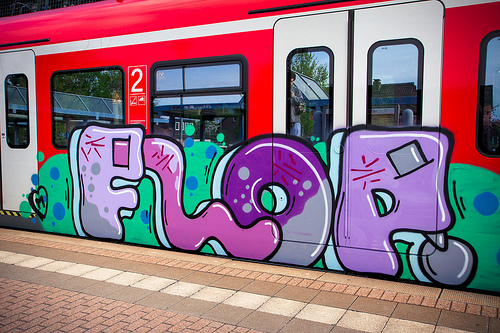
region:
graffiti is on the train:
[12, 76, 484, 291]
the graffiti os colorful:
[20, 74, 482, 317]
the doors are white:
[262, 8, 433, 257]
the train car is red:
[0, 1, 478, 171]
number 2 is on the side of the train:
[100, 54, 171, 123]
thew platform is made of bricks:
[57, 250, 329, 325]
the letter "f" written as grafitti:
[66, 124, 146, 242]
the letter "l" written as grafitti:
[140, 134, 282, 261]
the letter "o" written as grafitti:
[211, 135, 330, 269]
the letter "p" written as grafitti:
[323, 121, 454, 281]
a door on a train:
[270, 0, 440, 255]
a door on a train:
[0, 49, 42, 219]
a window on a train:
[48, 65, 124, 150]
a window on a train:
[150, 57, 248, 152]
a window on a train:
[372, 42, 419, 157]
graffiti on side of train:
[63, 118, 144, 241]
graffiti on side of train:
[136, 134, 283, 268]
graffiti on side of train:
[221, 133, 333, 262]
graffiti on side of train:
[340, 124, 450, 279]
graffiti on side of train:
[420, 223, 469, 287]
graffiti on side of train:
[21, 148, 78, 233]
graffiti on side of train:
[119, 170, 164, 246]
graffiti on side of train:
[386, 153, 493, 297]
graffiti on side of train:
[28, 119, 499, 303]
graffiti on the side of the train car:
[27, 110, 497, 277]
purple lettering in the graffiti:
[67, 128, 468, 280]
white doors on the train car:
[1, 18, 453, 285]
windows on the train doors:
[4, 43, 427, 183]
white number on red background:
[130, 68, 149, 96]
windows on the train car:
[51, 34, 499, 166]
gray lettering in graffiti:
[388, 139, 476, 284]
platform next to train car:
[2, 226, 489, 331]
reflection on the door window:
[291, 55, 324, 137]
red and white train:
[3, 5, 499, 280]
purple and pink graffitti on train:
[70, 126, 455, 246]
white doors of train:
[275, 1, 443, 258]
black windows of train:
[52, 30, 498, 168]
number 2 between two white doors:
[126, 64, 146, 94]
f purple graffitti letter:
[69, 125, 139, 236]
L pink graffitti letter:
[101, 137, 283, 260]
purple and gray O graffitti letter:
[211, 138, 333, 265]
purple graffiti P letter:
[328, 122, 450, 279]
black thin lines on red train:
[0, 0, 343, 48]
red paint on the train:
[6, 5, 496, 150]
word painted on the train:
[51, 120, 469, 259]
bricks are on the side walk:
[3, 259, 265, 331]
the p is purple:
[332, 94, 461, 279]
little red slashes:
[271, 150, 301, 190]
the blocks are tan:
[154, 273, 200, 308]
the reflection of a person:
[279, 63, 309, 140]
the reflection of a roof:
[1, 80, 124, 121]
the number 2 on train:
[124, 58, 151, 96]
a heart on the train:
[20, 181, 62, 219]